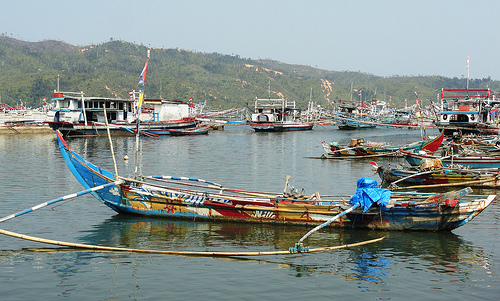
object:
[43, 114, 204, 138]
boat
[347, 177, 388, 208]
tarp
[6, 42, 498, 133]
distance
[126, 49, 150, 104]
flag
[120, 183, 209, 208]
stripes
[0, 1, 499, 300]
background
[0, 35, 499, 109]
vegetation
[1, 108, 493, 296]
water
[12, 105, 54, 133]
dock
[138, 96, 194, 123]
white building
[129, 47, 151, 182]
colorful flag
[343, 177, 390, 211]
an outrigger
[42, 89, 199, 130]
boat harbor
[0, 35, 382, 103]
green mountains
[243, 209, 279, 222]
nille on the boat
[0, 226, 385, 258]
long bamboo stick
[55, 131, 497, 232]
blue tip of boat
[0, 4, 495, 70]
hazy sky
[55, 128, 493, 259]
boat going down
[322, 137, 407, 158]
all canoe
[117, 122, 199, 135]
small canoe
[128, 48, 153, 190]
flag pole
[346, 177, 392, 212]
blue tarp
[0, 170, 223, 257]
balancing rails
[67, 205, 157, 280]
reflection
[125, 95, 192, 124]
house boat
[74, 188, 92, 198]
blue stripes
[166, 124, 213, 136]
boat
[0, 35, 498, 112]
mountains covered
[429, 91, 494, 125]
large white boat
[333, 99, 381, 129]
large white boat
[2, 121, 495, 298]
large body of water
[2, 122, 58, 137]
edge of the water